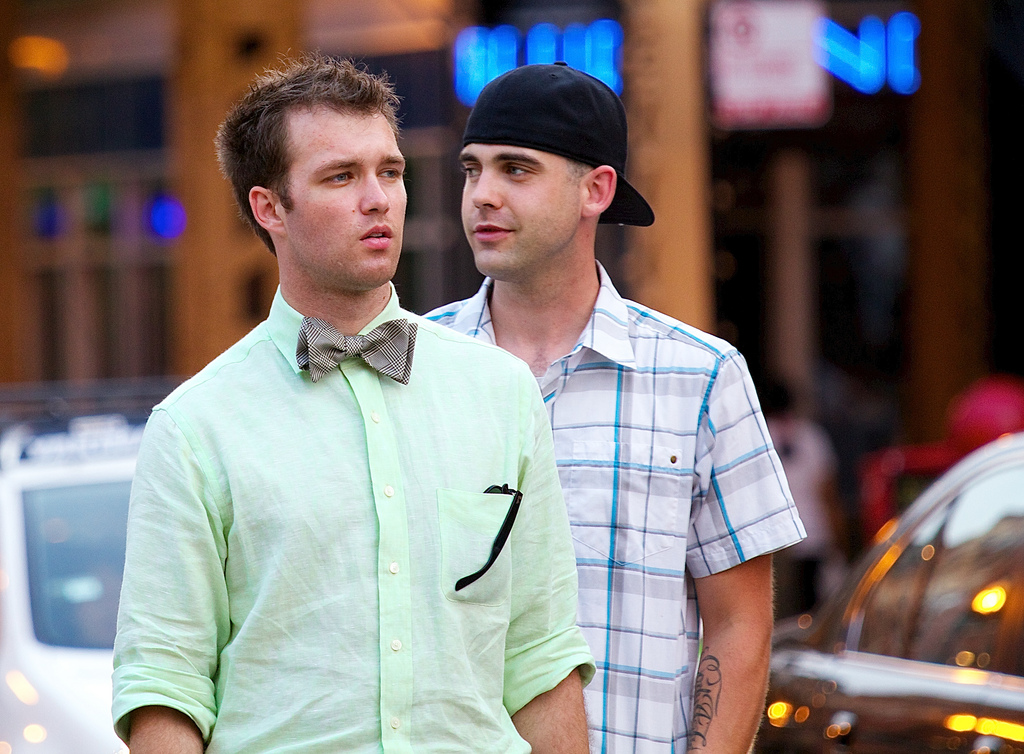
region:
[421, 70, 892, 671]
Man wearing a black hat backwards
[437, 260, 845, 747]
The shirt is blue and white plaid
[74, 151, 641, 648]
Black glasses in the shirt pocket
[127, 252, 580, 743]
The shirt is button down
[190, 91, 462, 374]
The man has a right ear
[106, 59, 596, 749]
guy wearing green shirt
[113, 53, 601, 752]
guy wearing bow tie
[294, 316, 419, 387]
bow tie is black and white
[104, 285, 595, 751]
sunglasses in shirt's pocket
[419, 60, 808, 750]
guy wearing a hat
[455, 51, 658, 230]
hat is on backwards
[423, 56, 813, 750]
guy wearing short sleeve shirt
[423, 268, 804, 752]
shirt has plaid pattern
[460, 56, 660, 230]
the cap is black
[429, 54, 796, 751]
tattoo on guy's arm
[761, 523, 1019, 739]
lights reflecting off of a car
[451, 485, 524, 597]
sunglasses are partially in a pocket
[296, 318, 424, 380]
black and white bow tie on man's neck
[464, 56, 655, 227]
black hat is on backwards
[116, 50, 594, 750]
man is wearing a green button up shirt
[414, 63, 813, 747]
man wearing blue and white plaid shirt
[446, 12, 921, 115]
blue neon lights in the background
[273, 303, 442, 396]
Bowtie worn by man in green shirt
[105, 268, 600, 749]
Green shirt worn by man with bowtie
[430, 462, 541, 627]
Glasses in shirt pocket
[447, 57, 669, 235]
Black hat worn by man in white and blue shirt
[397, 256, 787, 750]
Blue and white shirt worn by man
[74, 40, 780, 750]
Two guys in city environment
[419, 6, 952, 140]
Out of focus blue neon sign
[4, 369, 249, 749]
Partial view of white car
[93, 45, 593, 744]
Man wearing a green shirt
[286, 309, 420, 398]
Bowtie is black and white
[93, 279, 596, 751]
Green shirt worn by man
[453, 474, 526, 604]
Sunglasses in the pocket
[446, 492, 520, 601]
Pocket of shirt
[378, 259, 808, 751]
Blue and white striped shirt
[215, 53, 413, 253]
Man's hair is brown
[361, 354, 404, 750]
Buttons on shirt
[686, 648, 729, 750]
Tattoo on man's arm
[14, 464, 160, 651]
Windshield of white vehicle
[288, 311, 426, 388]
beige bow tie on mint green shirt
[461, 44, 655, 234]
black cap worn backwards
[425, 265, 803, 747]
white shirt with a grey and blue plaid print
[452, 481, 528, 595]
bow opf black framed glasses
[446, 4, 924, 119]
blue neon lights behind a column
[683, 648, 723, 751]
tattoo inside a forearm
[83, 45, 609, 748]
man wearing bow tie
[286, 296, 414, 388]
green patterned bow tie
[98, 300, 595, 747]
light green button shirt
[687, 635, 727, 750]
black tattoo on arm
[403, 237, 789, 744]
white and blue plaid shirt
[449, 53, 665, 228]
backwards black baseball hat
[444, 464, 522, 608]
black sunglasses pocket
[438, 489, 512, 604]
green shirt pocket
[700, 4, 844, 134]
white sign in background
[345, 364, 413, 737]
row of white buttons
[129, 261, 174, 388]
A window on a building.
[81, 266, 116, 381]
A window on a building.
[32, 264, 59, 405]
A window on a building.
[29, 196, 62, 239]
A window on a building.